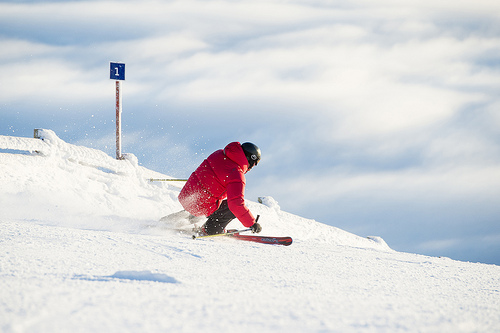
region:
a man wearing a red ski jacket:
[144, 126, 329, 276]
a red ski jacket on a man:
[184, 147, 309, 286]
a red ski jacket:
[154, 140, 326, 294]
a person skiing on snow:
[145, 127, 345, 289]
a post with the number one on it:
[9, 54, 199, 187]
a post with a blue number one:
[79, 50, 184, 222]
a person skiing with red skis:
[142, 120, 329, 266]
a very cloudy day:
[46, 10, 498, 169]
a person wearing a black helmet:
[134, 128, 301, 265]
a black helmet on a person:
[141, 120, 326, 272]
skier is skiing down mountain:
[158, 128, 313, 263]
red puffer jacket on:
[170, 127, 265, 237]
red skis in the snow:
[171, 205, 311, 255]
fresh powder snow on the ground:
[5, 115, 480, 325]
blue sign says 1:
[97, 36, 137, 166]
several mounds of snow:
[26, 117, 141, 182]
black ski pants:
[191, 195, 276, 256]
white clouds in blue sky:
[0, 0, 495, 225]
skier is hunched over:
[171, 111, 298, 256]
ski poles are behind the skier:
[149, 159, 289, 257]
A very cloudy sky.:
[170, 3, 422, 130]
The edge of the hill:
[258, 198, 488, 288]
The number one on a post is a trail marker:
[99, 40, 131, 167]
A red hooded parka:
[179, 130, 251, 213]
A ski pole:
[191, 221, 257, 246]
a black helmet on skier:
[233, 121, 273, 176]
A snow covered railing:
[0, 119, 155, 180]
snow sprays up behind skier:
[156, 179, 216, 242]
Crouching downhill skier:
[135, 125, 296, 235]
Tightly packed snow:
[13, 232, 420, 320]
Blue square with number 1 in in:
[101, 55, 141, 96]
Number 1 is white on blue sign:
[102, 54, 147, 116]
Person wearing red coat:
[193, 125, 259, 230]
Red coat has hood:
[209, 121, 252, 196]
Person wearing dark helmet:
[241, 135, 269, 182]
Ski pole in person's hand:
[204, 219, 282, 257]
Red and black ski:
[243, 210, 287, 279]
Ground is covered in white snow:
[82, 247, 227, 330]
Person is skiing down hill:
[120, 100, 288, 268]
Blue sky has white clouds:
[256, 40, 402, 195]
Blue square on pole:
[105, 50, 138, 119]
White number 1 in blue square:
[99, 62, 115, 80]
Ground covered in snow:
[98, 193, 183, 319]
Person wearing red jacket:
[162, 152, 279, 232]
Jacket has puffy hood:
[221, 117, 258, 207]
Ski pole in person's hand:
[203, 206, 258, 238]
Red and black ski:
[225, 197, 324, 285]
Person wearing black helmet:
[233, 129, 275, 218]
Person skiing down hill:
[65, 170, 214, 294]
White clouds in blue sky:
[249, 57, 394, 219]